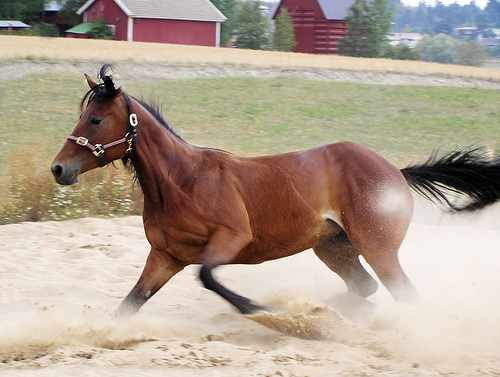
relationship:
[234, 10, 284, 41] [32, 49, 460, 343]
shrubery behind horse